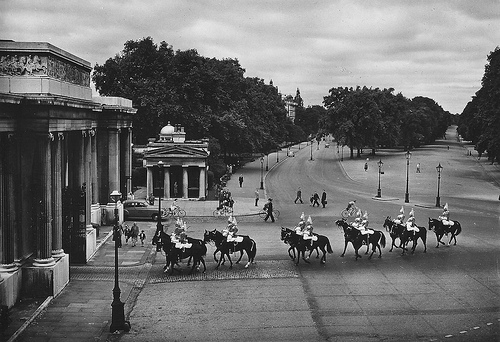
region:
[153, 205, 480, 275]
line of horses crossing street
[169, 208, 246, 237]
people on horses crossing street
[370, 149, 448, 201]
lights in middle of street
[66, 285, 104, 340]
sidewalk near the street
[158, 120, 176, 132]
dome on top of building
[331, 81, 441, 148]
trees in middle of street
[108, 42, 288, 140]
trees near the building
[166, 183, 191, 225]
person on a bike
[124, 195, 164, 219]
vehicle on the road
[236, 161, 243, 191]
person on the sidewalk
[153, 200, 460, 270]
guards on horses riding up to the gate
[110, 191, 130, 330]
a black lamp post in the foreground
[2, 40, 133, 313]
large building on the left with the columns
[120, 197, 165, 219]
a car at the intersection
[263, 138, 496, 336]
a road coming down the hill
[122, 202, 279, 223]
a street coming from the left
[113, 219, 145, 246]
a family waking by the big building on left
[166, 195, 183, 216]
bicycle in front of the car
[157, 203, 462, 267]
11 men on dark colored horses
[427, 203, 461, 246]
one horse in the alone at the back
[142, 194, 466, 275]
line of horses crossing street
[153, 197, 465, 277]
group of people in pointed hats on horses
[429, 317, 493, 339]
white dotted dashes painted on street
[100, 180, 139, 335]
street light on pavement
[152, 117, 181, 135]
dome on top of building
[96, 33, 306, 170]
large tall trees bordering sidewalk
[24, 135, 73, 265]
pillars on front of building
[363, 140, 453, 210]
three streetlights bordering street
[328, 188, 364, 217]
person on bicycle crossing street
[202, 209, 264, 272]
kkk members on horses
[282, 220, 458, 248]
horses walking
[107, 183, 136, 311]
a street light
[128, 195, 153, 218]
a car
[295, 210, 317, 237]
people on the horses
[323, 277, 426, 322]
the street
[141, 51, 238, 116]
the bushes are green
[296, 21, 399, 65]
the sky is cloudy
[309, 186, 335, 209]
people crossing the street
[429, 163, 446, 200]
a light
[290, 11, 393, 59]
clouds in the sky are white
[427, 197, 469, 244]
a man on a horse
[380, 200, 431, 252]
a man on a horse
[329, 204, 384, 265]
a man on a horse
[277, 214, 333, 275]
a man on a horse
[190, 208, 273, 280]
a man on a horse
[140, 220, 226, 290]
a man on a horse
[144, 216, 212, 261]
a man on a horse